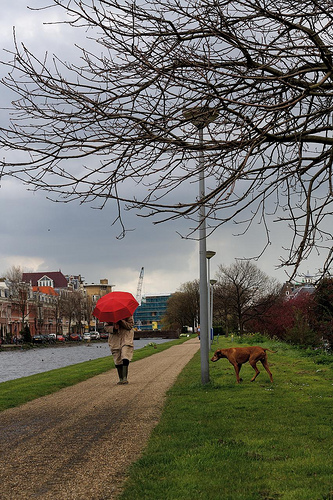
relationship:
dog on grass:
[204, 332, 280, 381] [189, 417, 299, 455]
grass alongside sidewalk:
[189, 417, 299, 455] [31, 397, 116, 426]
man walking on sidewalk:
[92, 286, 141, 387] [31, 397, 116, 426]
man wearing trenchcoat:
[92, 286, 141, 387] [109, 334, 141, 360]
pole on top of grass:
[164, 82, 217, 386] [189, 417, 299, 455]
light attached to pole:
[171, 96, 225, 131] [164, 82, 217, 386]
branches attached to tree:
[38, 84, 130, 165] [221, 152, 228, 276]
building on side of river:
[140, 291, 183, 327] [17, 346, 68, 360]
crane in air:
[127, 259, 152, 297] [40, 29, 86, 45]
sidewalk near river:
[31, 397, 116, 426] [17, 346, 68, 360]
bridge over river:
[133, 322, 182, 345] [17, 346, 68, 360]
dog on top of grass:
[204, 332, 280, 381] [189, 417, 299, 455]